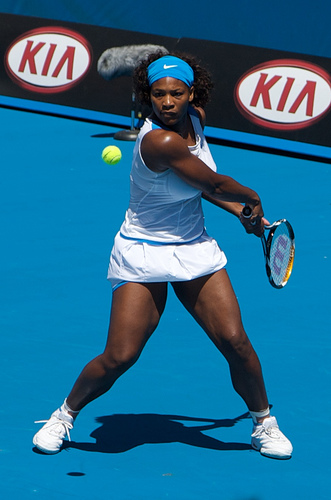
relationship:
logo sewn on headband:
[155, 61, 177, 73] [144, 56, 193, 86]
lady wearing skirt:
[16, 52, 301, 457] [104, 231, 237, 293]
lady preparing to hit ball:
[33, 52, 295, 461] [99, 143, 123, 165]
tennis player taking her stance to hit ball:
[33, 48, 293, 458] [101, 145, 121, 164]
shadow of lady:
[51, 394, 276, 465] [33, 52, 295, 461]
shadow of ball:
[66, 467, 87, 477] [99, 143, 123, 165]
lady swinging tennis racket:
[33, 52, 295, 461] [241, 205, 295, 289]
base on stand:
[73, 111, 141, 154] [88, 49, 176, 144]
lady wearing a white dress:
[33, 52, 295, 461] [106, 110, 227, 284]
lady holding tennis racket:
[33, 52, 295, 461] [241, 205, 295, 289]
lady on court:
[33, 52, 295, 461] [0, 103, 329, 497]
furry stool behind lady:
[97, 42, 168, 131] [33, 52, 295, 461]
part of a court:
[13, 171, 111, 278] [6, 26, 321, 461]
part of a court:
[51, 191, 82, 218] [0, 103, 329, 497]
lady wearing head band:
[33, 52, 295, 461] [137, 54, 194, 88]